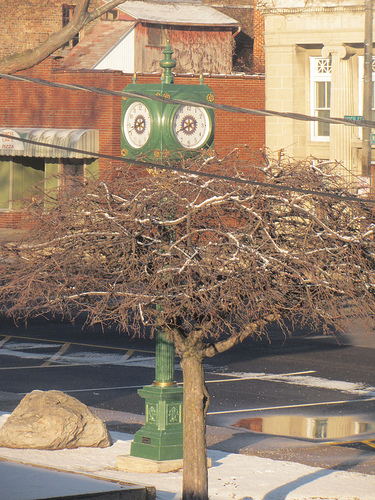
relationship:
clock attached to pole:
[112, 93, 160, 154] [128, 165, 189, 461]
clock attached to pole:
[160, 87, 215, 153] [128, 165, 189, 461]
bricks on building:
[228, 130, 262, 144] [0, 55, 273, 259]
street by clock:
[4, 269, 374, 462] [112, 93, 160, 154]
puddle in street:
[230, 402, 373, 442] [4, 269, 374, 462]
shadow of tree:
[255, 449, 369, 499] [3, 148, 373, 498]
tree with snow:
[3, 148, 373, 498] [182, 180, 243, 200]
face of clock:
[178, 103, 210, 147] [160, 87, 215, 153]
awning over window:
[2, 116, 98, 161] [2, 161, 100, 213]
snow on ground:
[257, 463, 292, 484] [18, 439, 363, 500]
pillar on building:
[323, 44, 360, 199] [254, 7, 374, 222]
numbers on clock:
[128, 104, 146, 115] [112, 93, 160, 154]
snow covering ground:
[182, 180, 243, 200] [18, 439, 363, 500]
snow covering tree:
[182, 180, 243, 200] [3, 148, 373, 498]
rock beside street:
[2, 384, 117, 456] [4, 269, 374, 462]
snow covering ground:
[257, 463, 292, 484] [18, 439, 363, 500]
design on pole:
[161, 403, 181, 427] [128, 165, 189, 461]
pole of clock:
[128, 165, 189, 461] [112, 93, 160, 154]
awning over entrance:
[2, 116, 98, 161] [10, 158, 47, 231]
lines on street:
[1, 330, 158, 382] [4, 269, 374, 462]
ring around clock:
[147, 378, 183, 389] [112, 93, 160, 154]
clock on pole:
[112, 93, 160, 154] [128, 165, 189, 461]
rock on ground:
[2, 384, 117, 456] [18, 439, 363, 500]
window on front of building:
[2, 161, 100, 213] [0, 55, 273, 259]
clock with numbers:
[112, 93, 160, 154] [128, 104, 146, 115]